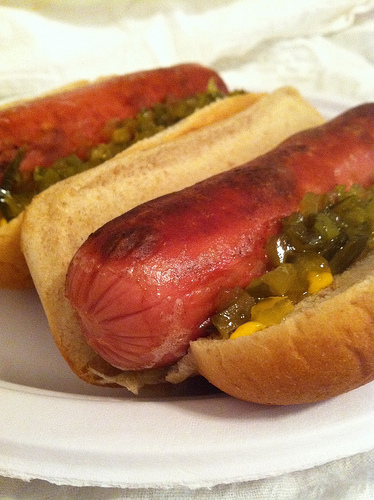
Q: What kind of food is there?
A: Sausage.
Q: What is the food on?
A: A plate.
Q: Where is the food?
A: On the table.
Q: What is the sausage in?
A: A Hot Dog bun.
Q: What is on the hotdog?
A: Mustard.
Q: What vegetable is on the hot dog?
A: Peppers.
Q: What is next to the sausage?
A: Another sausage.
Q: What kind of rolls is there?
A: Wheat rolls.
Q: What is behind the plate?
A: Napkins.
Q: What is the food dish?
A: Hot Dogs.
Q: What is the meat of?
A: Hotdog meat.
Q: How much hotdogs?
A: 2.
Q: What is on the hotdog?
A: Relish and mustard.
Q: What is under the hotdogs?
A: Plate.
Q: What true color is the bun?
A: Tan.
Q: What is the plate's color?
A: White.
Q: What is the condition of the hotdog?
A: Cooked.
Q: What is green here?
A: Relish.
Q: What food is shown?
A: Hot dog?.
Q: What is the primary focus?
A: Food.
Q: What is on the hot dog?
A: Relish.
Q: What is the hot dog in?
A: Bun?.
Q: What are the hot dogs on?
A: Plate.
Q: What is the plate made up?
A: Paper.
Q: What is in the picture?
A: Food.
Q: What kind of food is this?
A: Hot dogs.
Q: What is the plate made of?
A: Paper.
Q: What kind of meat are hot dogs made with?
A: Beef.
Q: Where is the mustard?
A: Underneath the hot dog.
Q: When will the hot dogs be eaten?
A: In a few minutes.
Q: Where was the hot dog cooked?
A: In the broiler.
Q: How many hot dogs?
A: Two.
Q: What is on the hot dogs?
A: Mustard and relish.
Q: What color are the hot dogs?
A: Brown.